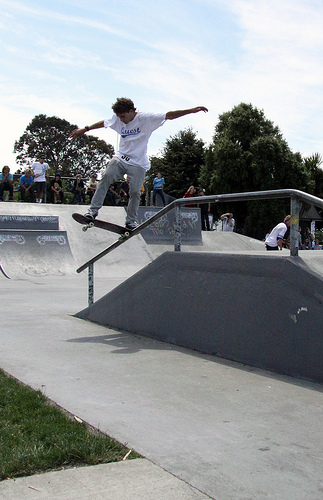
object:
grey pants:
[84, 158, 148, 227]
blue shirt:
[18, 172, 33, 188]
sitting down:
[18, 168, 39, 197]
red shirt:
[182, 185, 197, 202]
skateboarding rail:
[75, 178, 320, 276]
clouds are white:
[253, 10, 312, 98]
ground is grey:
[0, 197, 323, 499]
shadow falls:
[62, 314, 187, 379]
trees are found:
[12, 108, 115, 199]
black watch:
[82, 121, 91, 131]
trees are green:
[151, 125, 211, 207]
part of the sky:
[34, 5, 323, 175]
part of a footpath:
[2, 287, 323, 480]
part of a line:
[152, 250, 289, 281]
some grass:
[88, 433, 92, 453]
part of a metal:
[76, 253, 97, 307]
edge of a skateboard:
[72, 210, 85, 227]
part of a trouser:
[91, 157, 118, 212]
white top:
[104, 109, 166, 170]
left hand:
[197, 105, 210, 114]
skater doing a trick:
[58, 74, 211, 234]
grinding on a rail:
[37, 170, 323, 263]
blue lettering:
[135, 127, 143, 135]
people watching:
[151, 163, 169, 209]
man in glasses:
[0, 165, 15, 203]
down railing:
[69, 187, 177, 276]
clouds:
[243, 2, 323, 46]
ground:
[0, 407, 79, 475]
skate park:
[0, 0, 323, 500]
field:
[0, 402, 86, 469]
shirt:
[103, 113, 167, 169]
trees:
[211, 101, 306, 191]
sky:
[0, 1, 323, 189]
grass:
[0, 366, 145, 478]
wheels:
[88, 222, 96, 231]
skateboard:
[72, 211, 134, 238]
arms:
[144, 104, 209, 128]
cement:
[135, 361, 302, 498]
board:
[71, 213, 140, 238]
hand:
[71, 124, 83, 142]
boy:
[70, 96, 208, 226]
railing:
[77, 186, 323, 302]